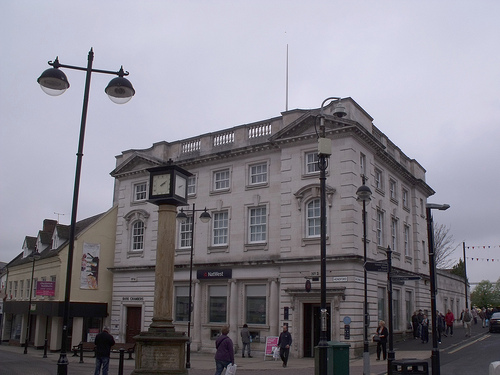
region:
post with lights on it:
[31, 29, 141, 370]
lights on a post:
[31, 53, 135, 113]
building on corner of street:
[100, 103, 476, 354]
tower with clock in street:
[135, 152, 203, 374]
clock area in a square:
[143, 155, 190, 211]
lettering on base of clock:
[139, 345, 180, 367]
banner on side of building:
[73, 238, 103, 297]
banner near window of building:
[29, 273, 58, 305]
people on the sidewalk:
[413, 305, 476, 340]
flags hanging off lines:
[468, 242, 498, 267]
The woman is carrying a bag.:
[214, 326, 238, 372]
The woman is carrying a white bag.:
[216, 323, 236, 373]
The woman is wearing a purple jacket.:
[212, 322, 237, 373]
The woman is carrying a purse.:
[214, 323, 229, 371]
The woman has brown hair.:
[214, 323, 234, 374]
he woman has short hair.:
[212, 326, 237, 373]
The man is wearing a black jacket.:
[88, 323, 113, 373]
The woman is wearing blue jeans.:
[211, 323, 237, 374]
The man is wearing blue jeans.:
[93, 324, 115, 373]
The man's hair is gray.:
[91, 323, 115, 373]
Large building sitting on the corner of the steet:
[109, 94, 431, 359]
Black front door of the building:
[301, 285, 330, 362]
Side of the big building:
[349, 92, 429, 357]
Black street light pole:
[63, 46, 96, 372]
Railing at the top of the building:
[168, 112, 280, 158]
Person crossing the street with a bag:
[272, 320, 293, 370]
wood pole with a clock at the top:
[146, 168, 189, 328]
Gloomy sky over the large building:
[0, 0, 497, 292]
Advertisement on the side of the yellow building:
[78, 240, 100, 292]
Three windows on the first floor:
[166, 277, 278, 328]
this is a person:
[80, 325, 121, 373]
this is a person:
[261, 305, 303, 370]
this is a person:
[375, 310, 397, 373]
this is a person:
[413, 304, 430, 340]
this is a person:
[414, 295, 437, 350]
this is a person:
[423, 299, 447, 359]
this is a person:
[437, 302, 461, 342]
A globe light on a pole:
[35, 67, 70, 95]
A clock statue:
[130, 157, 191, 372]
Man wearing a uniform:
[278, 325, 291, 367]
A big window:
[245, 203, 267, 244]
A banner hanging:
[80, 241, 99, 288]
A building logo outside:
[195, 268, 231, 278]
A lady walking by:
[372, 319, 387, 360]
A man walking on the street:
[93, 326, 113, 373]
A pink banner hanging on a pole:
[37, 278, 57, 298]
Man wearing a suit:
[459, 308, 474, 338]